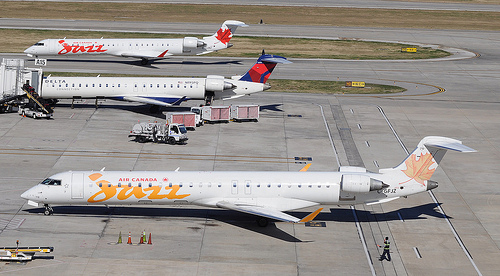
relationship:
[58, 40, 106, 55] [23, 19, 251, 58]
logo on aeroplane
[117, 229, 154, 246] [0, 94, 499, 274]
cones on tarmac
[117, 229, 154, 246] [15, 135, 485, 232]
cones near plane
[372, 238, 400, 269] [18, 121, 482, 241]
man near plane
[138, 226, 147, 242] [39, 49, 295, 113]
man near aeroplane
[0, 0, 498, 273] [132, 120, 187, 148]
airport has truck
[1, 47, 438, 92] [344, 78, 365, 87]
runway has sign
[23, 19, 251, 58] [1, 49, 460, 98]
aeroplane on runway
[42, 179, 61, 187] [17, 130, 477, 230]
glass in front of airplane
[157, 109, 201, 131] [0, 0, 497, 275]
container in airport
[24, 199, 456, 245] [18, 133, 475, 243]
shadow on aeroplane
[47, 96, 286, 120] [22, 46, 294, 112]
shadow on aeroplane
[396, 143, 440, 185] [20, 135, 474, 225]
leaf on aeroplane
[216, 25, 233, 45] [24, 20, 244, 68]
leaf on plane